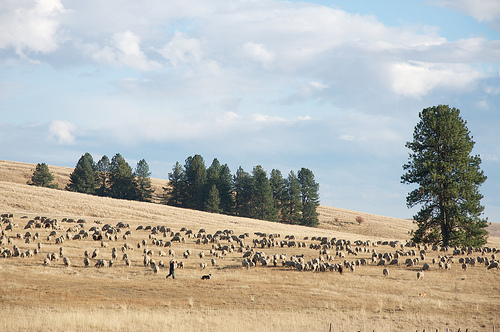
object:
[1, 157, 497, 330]
field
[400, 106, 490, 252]
tree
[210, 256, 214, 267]
sheep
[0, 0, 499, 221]
sky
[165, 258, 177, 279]
person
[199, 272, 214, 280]
dog